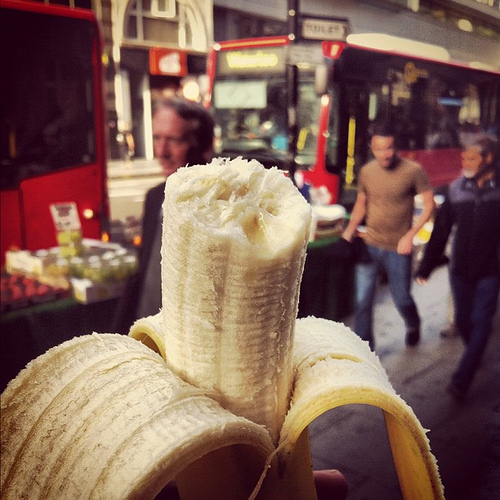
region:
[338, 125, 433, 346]
man in brown shirt walking on a sidewalk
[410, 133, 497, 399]
someone walking on a sidewalk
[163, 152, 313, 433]
banana with bite taken out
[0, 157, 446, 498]
a peeled banana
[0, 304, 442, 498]
a yellow banana peel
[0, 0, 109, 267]
back of a red bus on street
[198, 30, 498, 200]
a red bus on the street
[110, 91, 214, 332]
a man walking on a sidewalk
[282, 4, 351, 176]
black and white street sign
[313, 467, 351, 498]
end of a person's finger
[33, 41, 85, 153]
window of a bus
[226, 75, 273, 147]
window of a bus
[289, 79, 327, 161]
window of a bus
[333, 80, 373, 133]
window of a bus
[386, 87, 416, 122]
window of a bus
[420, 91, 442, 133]
window of a bus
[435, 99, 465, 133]
window of a bus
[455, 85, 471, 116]
window of a bus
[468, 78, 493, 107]
window of a bus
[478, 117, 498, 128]
window of a bus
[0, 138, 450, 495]
half eaten banana with peel on it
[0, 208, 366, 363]
fruit stall in the back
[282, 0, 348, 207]
pole with a toilet sign on it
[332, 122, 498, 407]
two people walking in the distance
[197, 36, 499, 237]
large london bus heading to waterloo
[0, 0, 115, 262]
another rear end of a london bus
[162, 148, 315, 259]
part where the banana was bit by the teeth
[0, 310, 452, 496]
peel of the banana taken off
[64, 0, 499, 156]
shops in the back around the street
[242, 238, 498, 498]
street on which the gentlemen are walking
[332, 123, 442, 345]
man in a brown shirt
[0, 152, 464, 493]
partially eaten banana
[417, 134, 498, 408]
man wearing a dark shirt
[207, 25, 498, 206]
red bus with large windows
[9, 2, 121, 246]
back of a red bus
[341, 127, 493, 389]
two men walking down the street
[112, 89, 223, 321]
man on the street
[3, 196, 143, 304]
canned produce for sale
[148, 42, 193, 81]
red storefront sign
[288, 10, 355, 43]
white sign for Toilets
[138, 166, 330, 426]
partially eaten banana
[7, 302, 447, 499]
peel of the banana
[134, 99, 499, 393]
men walking down the sidewalk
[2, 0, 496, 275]
two red buses stopped on the street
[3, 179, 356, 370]
table on the sidewalk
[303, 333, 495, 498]
sidewalk the men are walking on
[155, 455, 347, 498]
hand holding the banana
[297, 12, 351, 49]
black and white street sign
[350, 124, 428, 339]
man wearing brown shirt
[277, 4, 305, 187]
black pole street sign is on